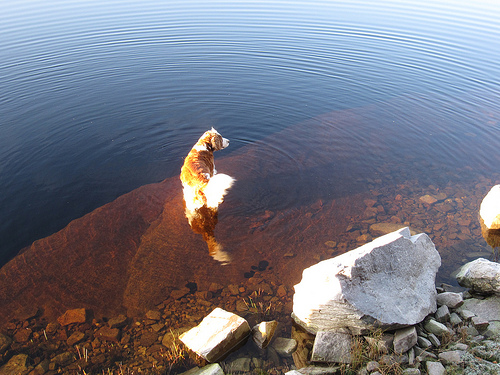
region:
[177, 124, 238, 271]
a dog in the water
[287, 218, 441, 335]
this rock is large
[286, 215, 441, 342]
the rock is white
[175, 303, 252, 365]
this rock is square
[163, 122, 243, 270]
this dog is brown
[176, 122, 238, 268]
this dog is white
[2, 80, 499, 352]
a ledge under the water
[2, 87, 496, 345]
the ledge is rock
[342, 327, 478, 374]
grass in the rocks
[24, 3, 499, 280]
ripples in the water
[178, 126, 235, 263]
A brown and white dog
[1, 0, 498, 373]
A body of water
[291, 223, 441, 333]
A large boulder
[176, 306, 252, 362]
A large rock in the water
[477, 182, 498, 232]
A large rock in the water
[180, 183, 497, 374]
A rocky shore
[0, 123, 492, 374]
A large group of rocks in the water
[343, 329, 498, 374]
some grass growing through the rocks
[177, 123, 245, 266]
A dog swimming in some water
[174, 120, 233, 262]
a dog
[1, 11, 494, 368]
water is clean and clear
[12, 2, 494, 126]
ripples formed in the water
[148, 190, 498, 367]
big stone on the shore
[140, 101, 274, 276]
dog is color brown and white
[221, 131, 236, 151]
snout of dog is white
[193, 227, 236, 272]
tail of dog is brown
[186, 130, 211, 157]
neck of dog is white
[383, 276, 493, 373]
small stones next big stone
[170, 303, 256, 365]
a rock skaped square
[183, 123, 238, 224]
this is a dog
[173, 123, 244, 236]
the dog is swimming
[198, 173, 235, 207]
this is the tail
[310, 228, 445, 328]
this is a rock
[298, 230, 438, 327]
the rock is big in size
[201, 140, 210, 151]
this is the ear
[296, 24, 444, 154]
the water is calm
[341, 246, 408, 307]
the rock is white in color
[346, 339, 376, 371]
the grass are short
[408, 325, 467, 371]
the rocks are small in size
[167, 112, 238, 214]
The dog is tan.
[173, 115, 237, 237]
The dog is in the water.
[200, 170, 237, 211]
His tail is white.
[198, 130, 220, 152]
He has a black collar.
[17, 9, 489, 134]
The water is calm.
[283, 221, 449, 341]
The rock is large.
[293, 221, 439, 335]
The rock is grey.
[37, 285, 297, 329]
Rocks are in the water.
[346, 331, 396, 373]
Grass is growing through the rocks.